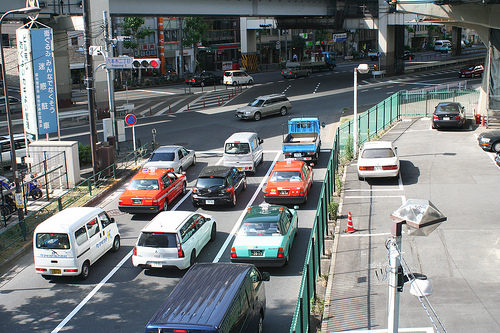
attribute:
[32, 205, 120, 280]
white van — large 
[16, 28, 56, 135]
sign — blue, white, cube shaped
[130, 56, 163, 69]
traffic light — horizontal, red, sideways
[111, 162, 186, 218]
taxi — red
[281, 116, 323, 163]
truck — light, blue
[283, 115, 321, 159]
truck — blue, a pick up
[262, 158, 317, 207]
red car — small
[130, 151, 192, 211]
taxi — brightly colored, orange, white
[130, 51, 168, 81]
light — red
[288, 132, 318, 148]
bed — empty, blue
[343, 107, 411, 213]
car — black, small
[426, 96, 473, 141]
car — black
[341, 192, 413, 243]
parking space — empty, designated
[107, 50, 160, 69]
white signal — traffic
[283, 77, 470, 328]
fence — green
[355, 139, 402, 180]
car — white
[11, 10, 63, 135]
sign — white, blue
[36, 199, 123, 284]
van — white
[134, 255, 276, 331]
grey house — black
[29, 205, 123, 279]
van — white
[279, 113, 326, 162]
truck — blue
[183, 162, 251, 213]
sedan — modern, black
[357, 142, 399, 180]
car — parked, white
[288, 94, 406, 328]
fence — green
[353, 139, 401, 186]
car — white, shinny, parked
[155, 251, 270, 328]
van — long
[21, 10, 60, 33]
lamp — street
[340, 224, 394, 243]
lines — white